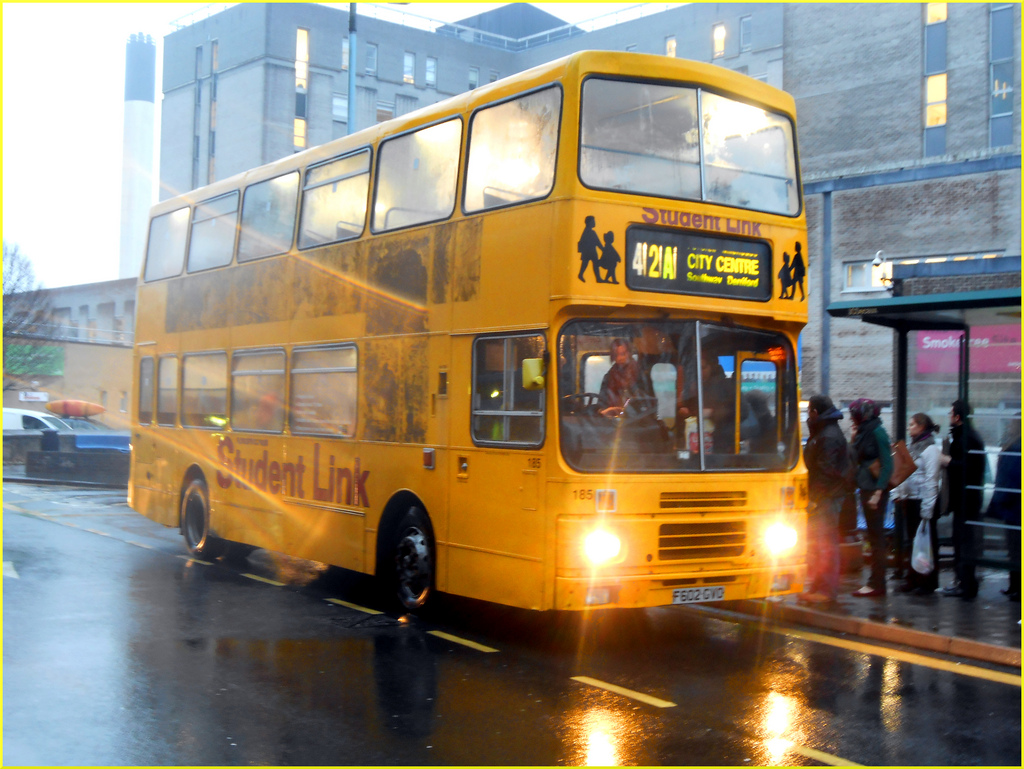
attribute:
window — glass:
[337, 109, 485, 254]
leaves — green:
[16, 288, 36, 347]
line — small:
[738, 718, 849, 764]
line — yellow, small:
[556, 666, 680, 721]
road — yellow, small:
[3, 474, 1012, 762]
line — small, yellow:
[424, 612, 505, 654]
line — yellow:
[314, 573, 395, 630]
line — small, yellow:
[232, 560, 302, 604]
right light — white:
[569, 519, 632, 571]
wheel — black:
[379, 482, 436, 614]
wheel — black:
[170, 469, 212, 552]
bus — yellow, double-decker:
[122, 48, 833, 617]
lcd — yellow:
[617, 229, 778, 299]